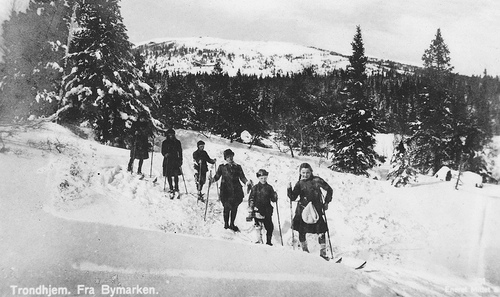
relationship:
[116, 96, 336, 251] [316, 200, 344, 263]
skiers holding ski pole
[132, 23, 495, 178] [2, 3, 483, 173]
trees along mountainside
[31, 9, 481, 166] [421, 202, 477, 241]
trees dusted with snow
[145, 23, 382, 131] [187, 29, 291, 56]
mountain covered in snow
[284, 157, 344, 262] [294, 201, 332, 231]
girl wearing skirt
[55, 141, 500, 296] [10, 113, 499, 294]
tracks in snow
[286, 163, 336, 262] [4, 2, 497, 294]
girl posing on mountainside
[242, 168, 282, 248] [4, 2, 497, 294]
skier posing on mountainside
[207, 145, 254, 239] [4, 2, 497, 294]
skier posing on mountainside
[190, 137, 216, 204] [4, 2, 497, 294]
skier posing on mountainside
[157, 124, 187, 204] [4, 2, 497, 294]
skier posing on mountainside